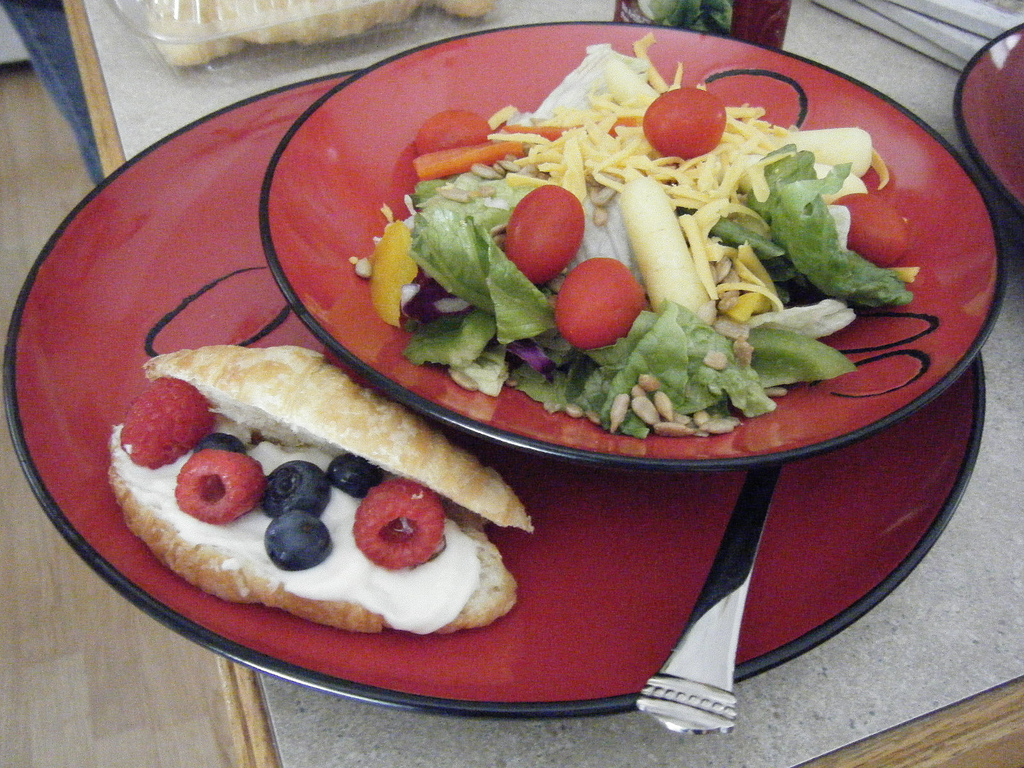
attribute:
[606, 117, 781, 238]
cheese — shredded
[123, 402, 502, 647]
cream cheese — white